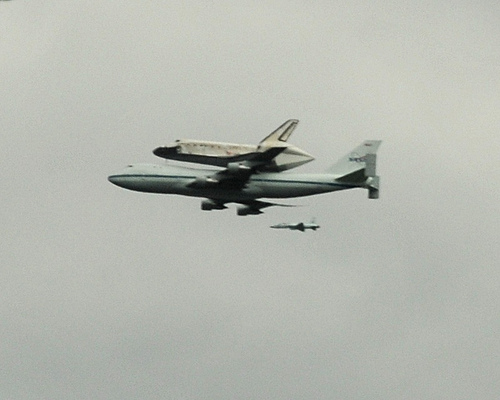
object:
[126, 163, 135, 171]
cockpit windows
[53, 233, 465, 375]
grey sky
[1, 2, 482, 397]
distance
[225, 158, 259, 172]
engine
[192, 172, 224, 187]
engine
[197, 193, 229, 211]
engine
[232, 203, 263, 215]
engine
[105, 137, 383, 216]
plane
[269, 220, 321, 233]
plane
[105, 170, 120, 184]
nose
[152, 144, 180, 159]
nose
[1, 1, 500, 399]
air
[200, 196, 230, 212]
turbine engine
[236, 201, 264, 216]
turbine engine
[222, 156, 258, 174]
turbine engine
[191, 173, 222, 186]
turbine engine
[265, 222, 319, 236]
airforce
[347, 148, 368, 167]
insignia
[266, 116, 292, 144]
part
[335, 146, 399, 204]
part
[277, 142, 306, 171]
part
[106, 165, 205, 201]
part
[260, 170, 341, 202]
part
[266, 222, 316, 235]
part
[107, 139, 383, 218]
airplane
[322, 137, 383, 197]
tail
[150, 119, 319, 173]
planes